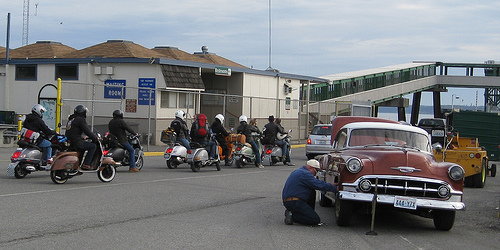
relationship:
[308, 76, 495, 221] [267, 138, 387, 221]
car in repair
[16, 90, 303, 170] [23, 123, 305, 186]
people riding bikes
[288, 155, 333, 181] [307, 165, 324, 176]
man wearing eyeglasses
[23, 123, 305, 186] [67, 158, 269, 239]
bikes on street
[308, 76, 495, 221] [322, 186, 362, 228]
car has tires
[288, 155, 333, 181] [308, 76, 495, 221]
man repairs car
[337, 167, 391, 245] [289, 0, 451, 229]
jack on bumper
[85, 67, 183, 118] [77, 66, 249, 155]
sign on walls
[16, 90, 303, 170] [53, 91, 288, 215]
fence on sidewalk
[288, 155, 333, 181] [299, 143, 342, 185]
man wearing cap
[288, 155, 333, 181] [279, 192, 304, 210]
man wearing belt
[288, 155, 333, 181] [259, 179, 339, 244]
man wearing jeans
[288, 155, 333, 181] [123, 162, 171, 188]
man wearing shoes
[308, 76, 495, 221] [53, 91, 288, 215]
car on sidewalk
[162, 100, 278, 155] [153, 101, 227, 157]
men has backpack